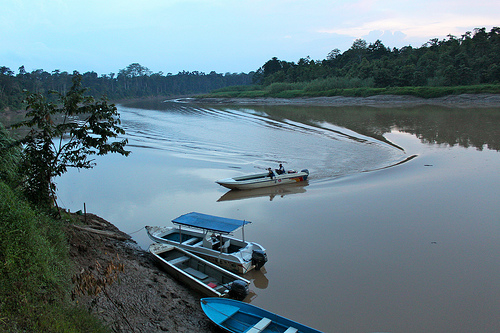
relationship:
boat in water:
[215, 161, 310, 192] [48, 99, 499, 331]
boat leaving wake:
[215, 161, 310, 192] [107, 103, 401, 181]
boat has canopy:
[141, 220, 272, 277] [173, 210, 251, 245]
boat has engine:
[215, 161, 310, 192] [301, 169, 310, 181]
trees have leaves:
[2, 20, 499, 170] [2, 26, 496, 187]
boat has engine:
[215, 161, 310, 192] [298, 166, 312, 190]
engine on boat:
[298, 166, 312, 190] [215, 161, 310, 192]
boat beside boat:
[149, 242, 249, 296] [215, 161, 310, 192]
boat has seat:
[215, 161, 310, 192] [273, 167, 287, 177]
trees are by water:
[2, 20, 499, 170] [48, 99, 499, 331]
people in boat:
[266, 158, 285, 178] [215, 161, 310, 192]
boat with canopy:
[141, 220, 272, 277] [173, 210, 251, 245]